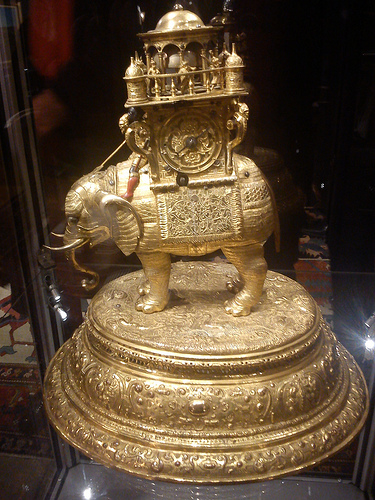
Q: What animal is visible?
A: Elephant.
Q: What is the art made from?
A: Metal.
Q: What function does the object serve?
A: Clock.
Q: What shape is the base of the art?
A: Circle.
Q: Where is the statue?
A: Inside of a display case.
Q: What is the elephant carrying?
A: A large structure with men on it.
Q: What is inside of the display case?
A: A statue of an elephant carrying a large structure.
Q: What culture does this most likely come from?
A: Asian.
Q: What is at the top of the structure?
A: A dome.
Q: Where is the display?
A: In a museum.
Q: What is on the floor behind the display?
A: Rug.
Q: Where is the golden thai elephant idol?
A: In the display case.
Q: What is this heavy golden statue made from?
A: Gold.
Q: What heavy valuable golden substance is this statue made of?
A: Gold.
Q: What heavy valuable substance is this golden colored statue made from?
A: Gold.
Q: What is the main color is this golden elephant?
A: Gold.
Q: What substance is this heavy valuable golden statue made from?
A: Gold.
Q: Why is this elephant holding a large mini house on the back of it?
A: Design.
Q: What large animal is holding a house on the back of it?
A: Elephant.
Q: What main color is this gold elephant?
A: Gold.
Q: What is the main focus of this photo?
A: Golden elephant on golden pedestal.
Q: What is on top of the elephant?
A: A golden building with windows.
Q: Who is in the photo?
A: Nobody.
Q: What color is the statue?
A: Gold.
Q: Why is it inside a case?
A: To protect it.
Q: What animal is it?
A: An elephant.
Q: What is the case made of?
A: Glass.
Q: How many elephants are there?
A: One.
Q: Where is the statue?
A: In the case.